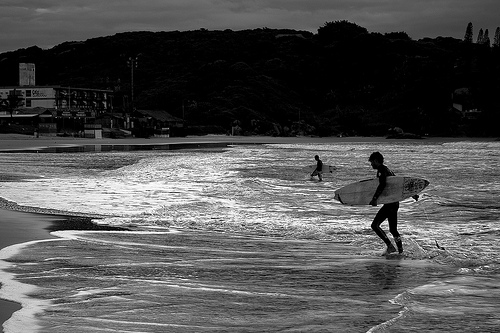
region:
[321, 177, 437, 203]
white surfboard in hand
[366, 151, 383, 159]
black hair on the person's head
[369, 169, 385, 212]
the man's left arm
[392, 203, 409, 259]
the man's left leg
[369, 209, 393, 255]
the person's right leg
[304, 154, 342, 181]
person carrying surfboard in water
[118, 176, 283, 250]
a body of water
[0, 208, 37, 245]
wet sand on the shore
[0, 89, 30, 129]
tree on the land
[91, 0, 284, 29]
grey clouds in the sky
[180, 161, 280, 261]
this is the water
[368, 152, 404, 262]
this is a man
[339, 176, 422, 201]
this is a surfing boat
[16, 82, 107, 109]
this is a building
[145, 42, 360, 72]
these are trees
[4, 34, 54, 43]
this is the sky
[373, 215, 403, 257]
these are the legs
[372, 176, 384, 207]
this is the hand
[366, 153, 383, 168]
this is the head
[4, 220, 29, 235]
this is the sand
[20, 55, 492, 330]
Some people are at the beach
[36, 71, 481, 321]
Some people are close to the water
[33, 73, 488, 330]
Some people are getting very wet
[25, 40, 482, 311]
Some people are carrying surfboards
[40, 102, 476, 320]
Some people are on their vacation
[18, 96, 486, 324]
Some people are doing some surfing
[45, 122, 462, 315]
Some people are coming in for the day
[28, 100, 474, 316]
Some people are at a beach resort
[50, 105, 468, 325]
Some people are out having fun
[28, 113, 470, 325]
Some people are enjoying the day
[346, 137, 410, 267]
Person carrying a surfboard in the water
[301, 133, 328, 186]
Person carrying a surfboard in the water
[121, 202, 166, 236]
Small ripples in the water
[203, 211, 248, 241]
Small ripples in the water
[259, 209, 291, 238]
Small ripples in the water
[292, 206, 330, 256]
Small ripples in the water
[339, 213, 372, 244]
Small ripples in the water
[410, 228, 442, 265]
Small ripples in the water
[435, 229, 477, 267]
Small ripples in the water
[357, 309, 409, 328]
Small ripples in the water